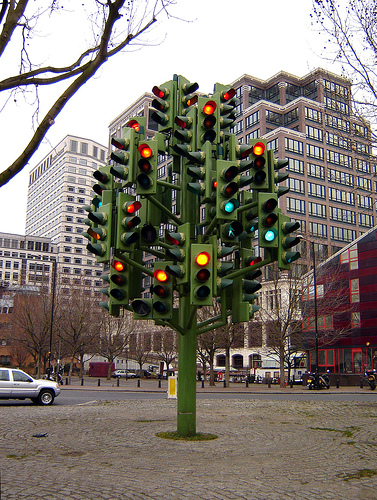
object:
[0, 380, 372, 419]
road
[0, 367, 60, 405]
car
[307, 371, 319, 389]
motorcycle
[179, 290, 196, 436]
pole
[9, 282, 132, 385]
tree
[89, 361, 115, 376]
wood posts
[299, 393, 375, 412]
ground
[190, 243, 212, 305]
traffic light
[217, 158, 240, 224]
traffic light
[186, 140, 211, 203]
traffic light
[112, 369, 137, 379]
car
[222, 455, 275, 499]
bricks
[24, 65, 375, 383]
buildings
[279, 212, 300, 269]
traffic light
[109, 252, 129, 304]
traffic light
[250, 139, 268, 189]
traffic light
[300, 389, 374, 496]
grass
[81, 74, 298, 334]
lights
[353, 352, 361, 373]
door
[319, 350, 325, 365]
window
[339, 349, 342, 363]
window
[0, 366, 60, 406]
van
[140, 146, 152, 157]
traffic light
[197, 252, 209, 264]
pole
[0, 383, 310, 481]
ground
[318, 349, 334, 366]
frames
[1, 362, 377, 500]
street